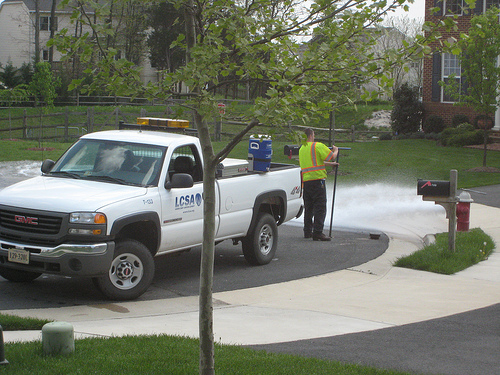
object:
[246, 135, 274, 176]
cooler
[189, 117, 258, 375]
truck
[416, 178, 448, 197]
mailbox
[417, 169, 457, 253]
post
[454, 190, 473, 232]
hydrant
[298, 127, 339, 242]
man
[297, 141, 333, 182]
shirt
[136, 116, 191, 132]
lights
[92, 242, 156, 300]
tire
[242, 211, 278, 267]
tire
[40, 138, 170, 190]
windshield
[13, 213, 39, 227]
letters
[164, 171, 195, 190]
left mirror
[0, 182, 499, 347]
sidewalk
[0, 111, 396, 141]
fence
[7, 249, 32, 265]
plate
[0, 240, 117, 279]
bumper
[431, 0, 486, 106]
shutters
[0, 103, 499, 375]
yard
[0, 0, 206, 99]
building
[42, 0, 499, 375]
tree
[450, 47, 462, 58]
leaves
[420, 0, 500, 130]
house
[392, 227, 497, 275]
grass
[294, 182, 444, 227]
water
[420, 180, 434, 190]
flag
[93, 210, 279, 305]
wheels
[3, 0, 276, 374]
left